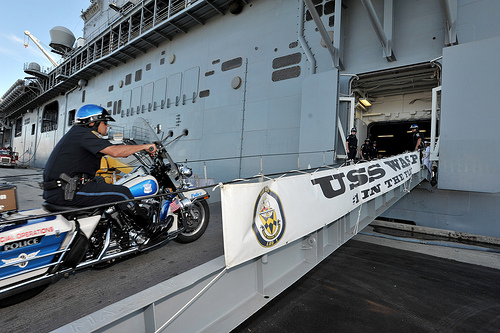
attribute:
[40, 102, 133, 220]
officer — police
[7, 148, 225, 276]
motorcycle — harley davidson, call operations, white, blue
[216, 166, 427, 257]
banner — white, identification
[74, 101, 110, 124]
helmet — blue, metallic, light blue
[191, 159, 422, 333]
ramp — boat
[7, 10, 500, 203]
boat — silver, port side, military, large, gray in color, light gray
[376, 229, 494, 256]
water — ocean, black, dark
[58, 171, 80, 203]
handgun — black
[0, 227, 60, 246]
letters — red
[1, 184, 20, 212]
box — cardboard, closed, brown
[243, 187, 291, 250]
emblem — uss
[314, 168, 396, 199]
letters — uss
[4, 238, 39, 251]
police — white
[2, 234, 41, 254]
sign — black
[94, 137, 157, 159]
arm — on right side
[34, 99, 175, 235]
policeman — call operations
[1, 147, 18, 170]
truck — parked, red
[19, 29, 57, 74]
crane — white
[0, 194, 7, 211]
stickers — white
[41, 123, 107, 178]
shirt — black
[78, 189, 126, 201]
stripe — blue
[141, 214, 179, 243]
boot — black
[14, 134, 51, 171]
cables — mooring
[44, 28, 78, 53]
stations — radar, ship